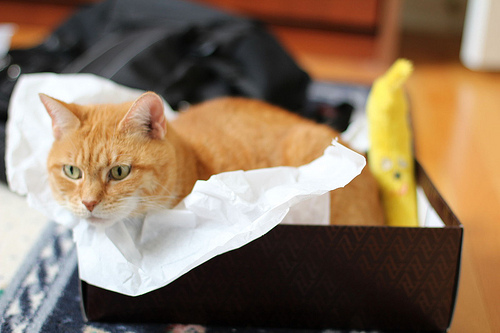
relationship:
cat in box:
[40, 90, 390, 226] [78, 224, 465, 327]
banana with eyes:
[365, 53, 420, 227] [107, 163, 137, 183]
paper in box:
[2, 70, 368, 300] [81, 145, 466, 324]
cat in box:
[40, 90, 390, 226] [81, 145, 466, 324]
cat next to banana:
[37, 89, 390, 226] [365, 56, 420, 227]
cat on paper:
[40, 90, 390, 226] [2, 70, 368, 300]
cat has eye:
[40, 90, 390, 226] [56, 159, 84, 184]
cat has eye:
[40, 90, 390, 226] [103, 160, 132, 182]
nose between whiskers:
[82, 196, 99, 209] [36, 196, 166, 220]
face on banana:
[371, 153, 416, 198] [365, 56, 420, 227]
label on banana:
[379, 153, 407, 189] [365, 56, 420, 227]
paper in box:
[2, 70, 368, 300] [76, 178, 467, 331]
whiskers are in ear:
[136, 104, 153, 128] [113, 89, 176, 139]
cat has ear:
[40, 90, 390, 226] [113, 89, 176, 139]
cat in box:
[40, 90, 390, 226] [73, 160, 466, 328]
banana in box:
[355, 47, 446, 210] [100, 194, 460, 305]